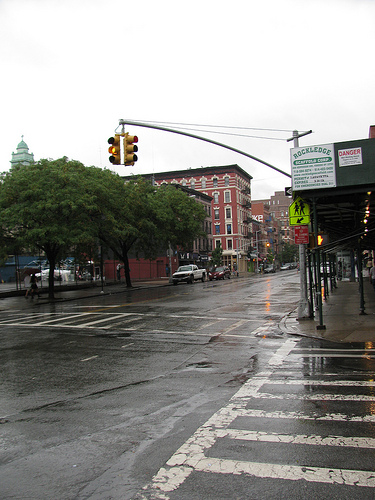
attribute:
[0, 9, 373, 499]
scene — rainy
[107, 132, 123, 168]
street light — yellow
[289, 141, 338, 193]
sign — white, green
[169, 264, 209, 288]
truck — white, parked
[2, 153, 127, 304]
tree — leafy, large, bushy, green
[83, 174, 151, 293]
tree — leafy, large, bushy, green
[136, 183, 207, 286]
tree — leafy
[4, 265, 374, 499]
street — wet, asphalt, black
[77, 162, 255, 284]
building — brick, red, large, apartment building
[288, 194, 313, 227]
sign — yellow, black, for crosswalk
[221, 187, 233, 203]
window — framed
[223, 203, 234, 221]
window — framed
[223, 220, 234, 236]
window — framed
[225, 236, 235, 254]
window — framed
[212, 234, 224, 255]
window — framed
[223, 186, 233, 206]
frame — white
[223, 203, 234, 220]
frame — white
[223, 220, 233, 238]
frame — white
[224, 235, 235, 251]
frame — white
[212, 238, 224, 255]
frame — white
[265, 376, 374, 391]
line — white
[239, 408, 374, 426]
line — white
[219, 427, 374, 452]
line — white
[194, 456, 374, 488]
line — white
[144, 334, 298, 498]
line — white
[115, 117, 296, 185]
post — overhanging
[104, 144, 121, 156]
light — yellow, lit up, signalling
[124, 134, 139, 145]
light — red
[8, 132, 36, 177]
tower — old-looking, grey, tall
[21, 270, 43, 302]
couple — walking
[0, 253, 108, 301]
fence — tall, wire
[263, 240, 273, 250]
light — orange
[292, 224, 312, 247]
traffic sign — red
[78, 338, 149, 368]
lines — broken, white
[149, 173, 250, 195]
decoration — white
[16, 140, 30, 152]
dome — green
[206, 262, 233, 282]
car — parked, red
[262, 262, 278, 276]
car — parked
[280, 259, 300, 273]
car — parked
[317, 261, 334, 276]
car — parked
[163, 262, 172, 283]
person — walking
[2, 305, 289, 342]
crosswalk — white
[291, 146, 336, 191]
lettering — green